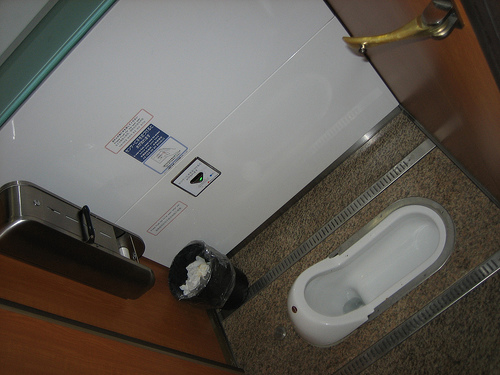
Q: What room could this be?
A: It is a bathroom.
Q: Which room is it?
A: It is a bathroom.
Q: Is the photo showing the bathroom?
A: Yes, it is showing the bathroom.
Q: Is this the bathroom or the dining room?
A: It is the bathroom.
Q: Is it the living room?
A: No, it is the bathroom.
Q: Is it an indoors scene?
A: Yes, it is indoors.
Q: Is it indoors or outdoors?
A: It is indoors.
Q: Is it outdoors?
A: No, it is indoors.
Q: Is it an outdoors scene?
A: No, it is indoors.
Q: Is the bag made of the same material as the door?
A: No, the bag is made of plastic and the door is made of wood.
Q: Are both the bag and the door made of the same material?
A: No, the bag is made of plastic and the door is made of wood.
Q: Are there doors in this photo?
A: Yes, there is a door.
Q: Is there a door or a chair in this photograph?
A: Yes, there is a door.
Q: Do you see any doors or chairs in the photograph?
A: Yes, there is a door.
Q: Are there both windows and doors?
A: No, there is a door but no windows.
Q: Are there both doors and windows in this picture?
A: No, there is a door but no windows.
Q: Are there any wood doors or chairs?
A: Yes, there is a wood door.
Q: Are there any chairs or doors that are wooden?
A: Yes, the door is wooden.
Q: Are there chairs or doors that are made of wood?
A: Yes, the door is made of wood.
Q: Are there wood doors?
A: Yes, there is a wood door.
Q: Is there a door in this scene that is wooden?
A: Yes, there is a door that is wooden.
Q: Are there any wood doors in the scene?
A: Yes, there is a door that is made of wood.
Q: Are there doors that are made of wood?
A: Yes, there is a door that is made of wood.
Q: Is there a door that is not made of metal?
A: Yes, there is a door that is made of wood.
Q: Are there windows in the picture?
A: No, there are no windows.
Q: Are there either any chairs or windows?
A: No, there are no windows or chairs.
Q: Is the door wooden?
A: Yes, the door is wooden.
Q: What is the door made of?
A: The door is made of wood.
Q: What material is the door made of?
A: The door is made of wood.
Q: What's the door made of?
A: The door is made of wood.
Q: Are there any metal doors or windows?
A: No, there is a door but it is wooden.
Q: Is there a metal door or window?
A: No, there is a door but it is wooden.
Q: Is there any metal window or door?
A: No, there is a door but it is wooden.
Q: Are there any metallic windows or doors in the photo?
A: No, there is a door but it is wooden.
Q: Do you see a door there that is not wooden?
A: No, there is a door but it is wooden.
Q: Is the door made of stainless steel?
A: No, the door is made of wood.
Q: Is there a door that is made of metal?
A: No, there is a door but it is made of wood.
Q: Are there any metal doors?
A: No, there is a door but it is made of wood.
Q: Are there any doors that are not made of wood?
A: No, there is a door but it is made of wood.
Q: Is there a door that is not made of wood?
A: No, there is a door but it is made of wood.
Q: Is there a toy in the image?
A: No, there are no toys.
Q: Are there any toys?
A: No, there are no toys.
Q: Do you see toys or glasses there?
A: No, there are no toys or glasses.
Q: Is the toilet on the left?
A: No, the toilet is on the right of the image.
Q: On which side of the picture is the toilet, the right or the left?
A: The toilet is on the right of the image.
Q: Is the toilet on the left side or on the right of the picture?
A: The toilet is on the right of the image.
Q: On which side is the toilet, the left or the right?
A: The toilet is on the right of the image.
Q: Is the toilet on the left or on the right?
A: The toilet is on the right of the image.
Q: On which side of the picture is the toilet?
A: The toilet is on the right of the image.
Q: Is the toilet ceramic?
A: Yes, the toilet is ceramic.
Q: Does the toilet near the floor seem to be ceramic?
A: Yes, the toilet is ceramic.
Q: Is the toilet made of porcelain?
A: Yes, the toilet is made of porcelain.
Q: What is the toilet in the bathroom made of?
A: The toilet is made of porcelain.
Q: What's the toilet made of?
A: The toilet is made of porcelain.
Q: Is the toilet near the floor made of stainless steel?
A: No, the toilet is made of porcelain.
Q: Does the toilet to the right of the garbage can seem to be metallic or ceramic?
A: The toilet is ceramic.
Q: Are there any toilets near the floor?
A: Yes, there is a toilet near the floor.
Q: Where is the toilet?
A: The toilet is in the bathroom.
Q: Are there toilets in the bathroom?
A: Yes, there is a toilet in the bathroom.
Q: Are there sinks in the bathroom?
A: No, there is a toilet in the bathroom.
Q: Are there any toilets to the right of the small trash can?
A: Yes, there is a toilet to the right of the trash can.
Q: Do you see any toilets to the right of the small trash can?
A: Yes, there is a toilet to the right of the trash can.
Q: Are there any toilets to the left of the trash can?
A: No, the toilet is to the right of the trash can.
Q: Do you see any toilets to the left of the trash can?
A: No, the toilet is to the right of the trash can.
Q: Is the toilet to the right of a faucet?
A: No, the toilet is to the right of a trash can.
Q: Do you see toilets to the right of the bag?
A: Yes, there is a toilet to the right of the bag.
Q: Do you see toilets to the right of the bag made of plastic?
A: Yes, there is a toilet to the right of the bag.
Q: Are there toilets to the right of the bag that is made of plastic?
A: Yes, there is a toilet to the right of the bag.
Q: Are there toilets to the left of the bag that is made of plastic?
A: No, the toilet is to the right of the bag.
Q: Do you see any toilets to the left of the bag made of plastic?
A: No, the toilet is to the right of the bag.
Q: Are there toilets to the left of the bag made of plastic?
A: No, the toilet is to the right of the bag.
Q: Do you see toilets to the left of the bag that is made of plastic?
A: No, the toilet is to the right of the bag.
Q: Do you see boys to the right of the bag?
A: No, there is a toilet to the right of the bag.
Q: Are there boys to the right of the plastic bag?
A: No, there is a toilet to the right of the bag.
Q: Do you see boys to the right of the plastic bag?
A: No, there is a toilet to the right of the bag.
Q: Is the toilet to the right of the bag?
A: Yes, the toilet is to the right of the bag.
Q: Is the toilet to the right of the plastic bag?
A: Yes, the toilet is to the right of the bag.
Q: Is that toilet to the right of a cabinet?
A: No, the toilet is to the right of the bag.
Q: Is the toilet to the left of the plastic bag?
A: No, the toilet is to the right of the bag.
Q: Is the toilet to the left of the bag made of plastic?
A: No, the toilet is to the right of the bag.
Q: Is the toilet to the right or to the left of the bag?
A: The toilet is to the right of the bag.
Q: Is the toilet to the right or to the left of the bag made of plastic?
A: The toilet is to the right of the bag.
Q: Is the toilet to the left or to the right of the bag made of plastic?
A: The toilet is to the right of the bag.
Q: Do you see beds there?
A: No, there are no beds.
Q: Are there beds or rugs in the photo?
A: No, there are no beds or rugs.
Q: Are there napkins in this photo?
A: No, there are no napkins.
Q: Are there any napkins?
A: No, there are no napkins.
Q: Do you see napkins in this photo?
A: No, there are no napkins.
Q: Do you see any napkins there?
A: No, there are no napkins.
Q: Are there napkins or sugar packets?
A: No, there are no napkins or sugar packets.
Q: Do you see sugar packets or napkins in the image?
A: No, there are no napkins or sugar packets.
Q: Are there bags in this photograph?
A: Yes, there is a bag.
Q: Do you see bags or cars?
A: Yes, there is a bag.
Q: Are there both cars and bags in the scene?
A: No, there is a bag but no cars.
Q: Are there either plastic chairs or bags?
A: Yes, there is a plastic bag.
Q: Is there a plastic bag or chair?
A: Yes, there is a plastic bag.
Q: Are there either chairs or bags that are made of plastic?
A: Yes, the bag is made of plastic.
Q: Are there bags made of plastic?
A: Yes, there is a bag that is made of plastic.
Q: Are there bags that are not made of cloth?
A: Yes, there is a bag that is made of plastic.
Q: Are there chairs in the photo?
A: No, there are no chairs.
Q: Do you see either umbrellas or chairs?
A: No, there are no chairs or umbrellas.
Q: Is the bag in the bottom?
A: Yes, the bag is in the bottom of the image.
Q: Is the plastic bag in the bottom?
A: Yes, the bag is in the bottom of the image.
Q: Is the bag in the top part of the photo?
A: No, the bag is in the bottom of the image.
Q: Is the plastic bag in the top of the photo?
A: No, the bag is in the bottom of the image.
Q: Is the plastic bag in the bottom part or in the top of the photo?
A: The bag is in the bottom of the image.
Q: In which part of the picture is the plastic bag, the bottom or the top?
A: The bag is in the bottom of the image.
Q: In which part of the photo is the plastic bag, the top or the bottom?
A: The bag is in the bottom of the image.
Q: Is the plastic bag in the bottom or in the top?
A: The bag is in the bottom of the image.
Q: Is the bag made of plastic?
A: Yes, the bag is made of plastic.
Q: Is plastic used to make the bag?
A: Yes, the bag is made of plastic.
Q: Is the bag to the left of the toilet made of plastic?
A: Yes, the bag is made of plastic.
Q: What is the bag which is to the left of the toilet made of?
A: The bag is made of plastic.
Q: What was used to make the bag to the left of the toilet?
A: The bag is made of plastic.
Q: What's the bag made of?
A: The bag is made of plastic.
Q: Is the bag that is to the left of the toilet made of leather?
A: No, the bag is made of plastic.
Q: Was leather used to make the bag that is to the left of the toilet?
A: No, the bag is made of plastic.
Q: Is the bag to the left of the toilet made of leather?
A: No, the bag is made of plastic.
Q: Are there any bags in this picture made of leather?
A: No, there is a bag but it is made of plastic.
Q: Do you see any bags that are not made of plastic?
A: No, there is a bag but it is made of plastic.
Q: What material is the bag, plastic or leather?
A: The bag is made of plastic.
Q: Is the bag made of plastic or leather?
A: The bag is made of plastic.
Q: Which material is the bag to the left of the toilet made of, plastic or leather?
A: The bag is made of plastic.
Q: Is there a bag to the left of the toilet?
A: Yes, there is a bag to the left of the toilet.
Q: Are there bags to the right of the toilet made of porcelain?
A: No, the bag is to the left of the toilet.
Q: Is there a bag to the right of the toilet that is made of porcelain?
A: No, the bag is to the left of the toilet.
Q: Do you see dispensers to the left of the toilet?
A: No, there is a bag to the left of the toilet.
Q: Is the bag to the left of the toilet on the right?
A: Yes, the bag is to the left of the toilet.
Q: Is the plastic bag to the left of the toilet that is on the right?
A: Yes, the bag is to the left of the toilet.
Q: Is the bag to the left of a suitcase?
A: No, the bag is to the left of the toilet.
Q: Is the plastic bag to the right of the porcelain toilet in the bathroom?
A: No, the bag is to the left of the toilet.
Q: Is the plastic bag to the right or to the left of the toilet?
A: The bag is to the left of the toilet.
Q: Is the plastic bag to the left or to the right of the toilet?
A: The bag is to the left of the toilet.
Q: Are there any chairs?
A: No, there are no chairs.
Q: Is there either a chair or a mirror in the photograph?
A: No, there are no chairs or mirrors.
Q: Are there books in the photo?
A: No, there are no books.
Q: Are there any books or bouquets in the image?
A: No, there are no books or bouquets.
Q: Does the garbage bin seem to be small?
A: Yes, the garbage bin is small.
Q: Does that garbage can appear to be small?
A: Yes, the garbage can is small.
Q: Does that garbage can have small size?
A: Yes, the garbage can is small.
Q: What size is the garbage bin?
A: The garbage bin is small.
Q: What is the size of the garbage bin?
A: The garbage bin is small.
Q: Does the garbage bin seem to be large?
A: No, the garbage bin is small.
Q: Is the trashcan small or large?
A: The trashcan is small.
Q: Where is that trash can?
A: The trash can is on the floor.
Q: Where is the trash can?
A: The trash can is on the floor.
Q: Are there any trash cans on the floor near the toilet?
A: Yes, there is a trash can on the floor.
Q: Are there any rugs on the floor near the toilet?
A: No, there is a trash can on the floor.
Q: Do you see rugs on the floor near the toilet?
A: No, there is a trash can on the floor.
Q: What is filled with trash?
A: The trashcan is filled with trash.